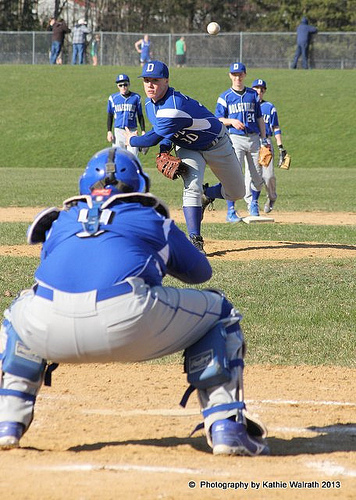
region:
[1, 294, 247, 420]
Gray pants in the foreground.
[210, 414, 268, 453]
Blue sport shoes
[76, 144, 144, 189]
A blue helmet for baseball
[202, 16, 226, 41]
A baseball in the air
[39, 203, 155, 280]
A blue jersey in the photo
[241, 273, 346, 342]
Green grass on the playing field.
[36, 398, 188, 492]
A dirt track at the playing field.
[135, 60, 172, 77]
A blue cap in the photo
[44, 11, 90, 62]
Two people standing near the fence.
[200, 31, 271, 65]
A mesh wire fence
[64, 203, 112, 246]
back of catchers strap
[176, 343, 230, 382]
rawlings shin guard for catchers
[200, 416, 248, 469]
back of blue heel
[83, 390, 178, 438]
white outline of home plate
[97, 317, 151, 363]
back pocket of catcher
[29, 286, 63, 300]
blue belt of catcher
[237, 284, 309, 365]
grass on baseball field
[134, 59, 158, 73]
logo on pitchers hat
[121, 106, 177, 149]
left arm of pitcher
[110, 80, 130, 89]
sunglasses on the shortstop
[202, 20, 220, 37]
White tennis ball flying through the air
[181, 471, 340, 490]
Black copyright note of the photographer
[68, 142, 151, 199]
Back of the catcher's blue helmet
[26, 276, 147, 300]
Catcher's blue belt through gray belt loops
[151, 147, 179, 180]
Dark brown pitcher's mitt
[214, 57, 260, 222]
Baseball player standing in the background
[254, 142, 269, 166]
Light brown baseball glove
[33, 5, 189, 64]
People standing on another field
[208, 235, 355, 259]
Shadow of the pitcher on the ground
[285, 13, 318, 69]
Person dressed all in blue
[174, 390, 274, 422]
blue straps on knee pad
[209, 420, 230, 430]
small white logo on sneakers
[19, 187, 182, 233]
padding over catcher's shoulders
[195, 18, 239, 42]
white baseball being thrown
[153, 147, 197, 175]
brown baseball glove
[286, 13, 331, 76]
man leaning over fence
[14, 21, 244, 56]
tall gray chain link fence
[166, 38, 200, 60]
green shirt with no sleeves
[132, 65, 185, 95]
shadow on player's face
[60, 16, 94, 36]
gray hoodie on man's back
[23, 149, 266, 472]
baseball player wearing blue and white uniform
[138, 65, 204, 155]
baseball player wearing blue and white uniform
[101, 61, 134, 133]
baseball player wearing blue and white uniform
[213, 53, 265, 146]
baseball player wearing blue and white uniform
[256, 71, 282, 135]
baseball player wearing blue and white uniform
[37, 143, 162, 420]
male baseball player wearing blue and white uniformbaseball player wearing blue and white uniform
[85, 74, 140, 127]
baseball player wearing blue and white uniform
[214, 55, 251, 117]
baseball player wearing blue and white uniform